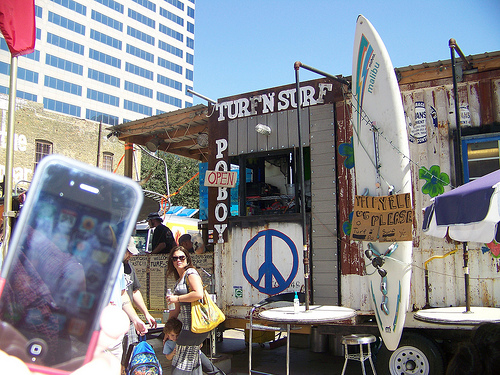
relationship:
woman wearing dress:
[163, 245, 230, 375] [169, 269, 211, 374]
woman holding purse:
[163, 245, 230, 375] [181, 274, 228, 333]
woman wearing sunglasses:
[163, 245, 230, 375] [170, 253, 190, 266]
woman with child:
[163, 245, 230, 375] [161, 314, 227, 375]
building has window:
[0, 0, 200, 129] [186, 34, 197, 50]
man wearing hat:
[142, 210, 180, 255] [146, 211, 165, 224]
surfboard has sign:
[347, 9, 416, 354] [345, 190, 416, 248]